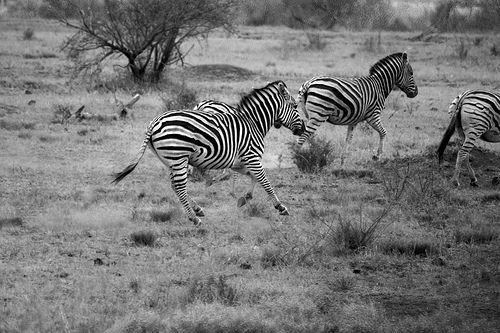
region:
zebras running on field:
[132, 35, 483, 252]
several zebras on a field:
[132, 19, 498, 243]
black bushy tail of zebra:
[117, 159, 134, 184]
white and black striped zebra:
[169, 114, 246, 163]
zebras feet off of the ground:
[178, 171, 301, 241]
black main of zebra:
[370, 50, 406, 71]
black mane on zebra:
[235, 85, 265, 110]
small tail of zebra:
[429, 109, 465, 164]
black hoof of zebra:
[265, 204, 292, 219]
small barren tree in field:
[68, 0, 177, 85]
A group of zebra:
[114, 43, 499, 228]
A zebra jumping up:
[118, 73, 311, 230]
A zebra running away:
[286, 49, 420, 164]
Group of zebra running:
[118, 40, 498, 223]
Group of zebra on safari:
[109, 36, 499, 251]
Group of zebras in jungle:
[93, 48, 499, 241]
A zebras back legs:
[165, 137, 216, 237]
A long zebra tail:
[106, 125, 166, 192]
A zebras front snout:
[384, 47, 422, 102]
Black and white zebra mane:
[366, 42, 404, 82]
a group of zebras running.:
[117, 47, 495, 223]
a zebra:
[143, 76, 303, 233]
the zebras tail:
[113, 162, 142, 185]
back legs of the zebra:
[170, 176, 211, 230]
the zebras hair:
[242, 89, 261, 99]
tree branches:
[108, 17, 186, 77]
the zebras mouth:
[406, 87, 421, 97]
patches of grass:
[126, 227, 165, 247]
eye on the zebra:
[405, 65, 416, 76]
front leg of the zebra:
[372, 111, 387, 160]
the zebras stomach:
[198, 145, 242, 168]